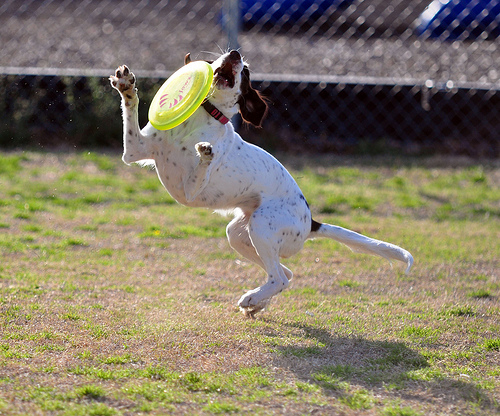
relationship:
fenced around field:
[2, 3, 498, 159] [6, 161, 496, 413]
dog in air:
[101, 35, 421, 325] [53, 26, 447, 391]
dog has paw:
[101, 35, 421, 325] [102, 57, 140, 97]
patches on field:
[84, 248, 220, 373] [6, 161, 496, 413]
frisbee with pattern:
[150, 60, 215, 123] [154, 80, 188, 107]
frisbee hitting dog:
[150, 60, 215, 123] [101, 52, 436, 318]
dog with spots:
[101, 35, 421, 325] [264, 190, 314, 215]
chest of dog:
[164, 160, 251, 220] [101, 35, 421, 325]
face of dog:
[187, 41, 255, 117] [101, 35, 421, 325]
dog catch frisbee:
[101, 35, 421, 325] [135, 46, 215, 136]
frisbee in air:
[150, 60, 215, 123] [269, 26, 373, 101]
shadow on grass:
[281, 307, 465, 414] [138, 365, 218, 395]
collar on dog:
[201, 100, 232, 128] [101, 35, 421, 325]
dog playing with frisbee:
[101, 35, 421, 325] [150, 60, 215, 123]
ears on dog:
[228, 62, 270, 132] [101, 35, 421, 325]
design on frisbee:
[152, 78, 192, 111] [148, 56, 213, 130]